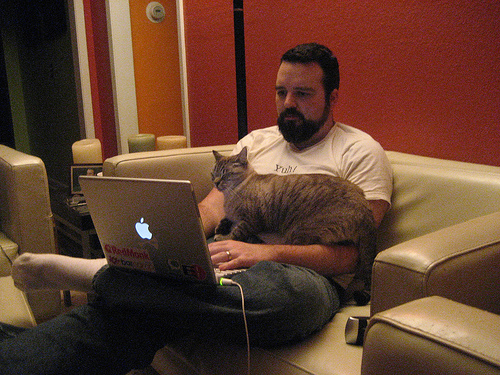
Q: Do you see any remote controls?
A: Yes, there is a remote control.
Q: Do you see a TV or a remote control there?
A: Yes, there is a remote control.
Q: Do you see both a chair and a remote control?
A: Yes, there are both a remote control and a chair.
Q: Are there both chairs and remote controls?
A: Yes, there are both a remote control and a chair.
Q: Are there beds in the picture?
A: No, there are no beds.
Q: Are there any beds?
A: No, there are no beds.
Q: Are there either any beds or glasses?
A: No, there are no beds or glasses.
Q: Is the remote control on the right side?
A: Yes, the remote control is on the right of the image.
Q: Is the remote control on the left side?
A: No, the remote control is on the right of the image.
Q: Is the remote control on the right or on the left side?
A: The remote control is on the right of the image.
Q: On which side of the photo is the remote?
A: The remote is on the right of the image.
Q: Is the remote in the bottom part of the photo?
A: Yes, the remote is in the bottom of the image.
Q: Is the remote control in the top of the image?
A: No, the remote control is in the bottom of the image.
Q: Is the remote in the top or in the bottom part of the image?
A: The remote is in the bottom of the image.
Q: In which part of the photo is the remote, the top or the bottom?
A: The remote is in the bottom of the image.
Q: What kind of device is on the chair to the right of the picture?
A: The device is a remote control.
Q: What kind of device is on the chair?
A: The device is a remote control.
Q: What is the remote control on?
A: The remote control is on the chair.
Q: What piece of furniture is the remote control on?
A: The remote control is on the chair.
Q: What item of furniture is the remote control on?
A: The remote control is on the chair.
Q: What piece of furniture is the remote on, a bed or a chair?
A: The remote is on a chair.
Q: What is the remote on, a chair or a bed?
A: The remote is on a chair.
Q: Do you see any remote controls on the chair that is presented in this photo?
A: Yes, there is a remote control on the chair.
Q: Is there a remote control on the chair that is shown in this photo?
A: Yes, there is a remote control on the chair.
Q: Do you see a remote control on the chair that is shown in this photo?
A: Yes, there is a remote control on the chair.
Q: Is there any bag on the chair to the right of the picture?
A: No, there is a remote control on the chair.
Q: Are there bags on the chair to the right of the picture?
A: No, there is a remote control on the chair.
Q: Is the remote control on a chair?
A: Yes, the remote control is on a chair.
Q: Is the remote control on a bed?
A: No, the remote control is on a chair.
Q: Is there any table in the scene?
A: Yes, there is a table.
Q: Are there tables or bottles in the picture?
A: Yes, there is a table.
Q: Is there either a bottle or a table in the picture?
A: Yes, there is a table.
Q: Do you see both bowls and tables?
A: No, there is a table but no bowls.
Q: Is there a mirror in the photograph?
A: No, there are no mirrors.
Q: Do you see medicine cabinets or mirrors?
A: No, there are no mirrors or medicine cabinets.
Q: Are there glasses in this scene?
A: No, there are no glasses.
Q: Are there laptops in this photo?
A: Yes, there is a laptop.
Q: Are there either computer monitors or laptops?
A: Yes, there is a laptop.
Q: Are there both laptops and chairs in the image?
A: Yes, there are both a laptop and a chair.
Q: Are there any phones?
A: No, there are no phones.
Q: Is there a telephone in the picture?
A: No, there are no phones.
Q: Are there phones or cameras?
A: No, there are no phones or cameras.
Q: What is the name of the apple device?
A: The device is a laptop.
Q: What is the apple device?
A: The device is a laptop.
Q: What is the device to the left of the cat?
A: The device is a laptop.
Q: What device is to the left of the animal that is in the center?
A: The device is a laptop.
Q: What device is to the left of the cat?
A: The device is a laptop.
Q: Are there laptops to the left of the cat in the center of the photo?
A: Yes, there is a laptop to the left of the cat.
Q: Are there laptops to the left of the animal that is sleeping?
A: Yes, there is a laptop to the left of the cat.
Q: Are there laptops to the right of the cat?
A: No, the laptop is to the left of the cat.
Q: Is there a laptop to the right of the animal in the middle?
A: No, the laptop is to the left of the cat.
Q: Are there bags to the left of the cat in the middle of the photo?
A: No, there is a laptop to the left of the cat.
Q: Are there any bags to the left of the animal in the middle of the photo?
A: No, there is a laptop to the left of the cat.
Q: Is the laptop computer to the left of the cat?
A: Yes, the laptop computer is to the left of the cat.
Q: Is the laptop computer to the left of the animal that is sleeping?
A: Yes, the laptop computer is to the left of the cat.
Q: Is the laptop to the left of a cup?
A: No, the laptop is to the left of the cat.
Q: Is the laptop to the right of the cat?
A: No, the laptop is to the left of the cat.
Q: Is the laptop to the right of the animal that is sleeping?
A: No, the laptop is to the left of the cat.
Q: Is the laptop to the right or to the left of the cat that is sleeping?
A: The laptop is to the left of the cat.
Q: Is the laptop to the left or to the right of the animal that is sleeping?
A: The laptop is to the left of the cat.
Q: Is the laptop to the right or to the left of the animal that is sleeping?
A: The laptop is to the left of the cat.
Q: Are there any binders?
A: No, there are no binders.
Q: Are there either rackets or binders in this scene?
A: No, there are no binders or rackets.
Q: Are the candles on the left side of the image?
A: Yes, the candles are on the left of the image.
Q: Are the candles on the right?
A: No, the candles are on the left of the image.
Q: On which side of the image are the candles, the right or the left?
A: The candles are on the left of the image.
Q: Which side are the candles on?
A: The candles are on the left of the image.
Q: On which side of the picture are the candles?
A: The candles are on the left of the image.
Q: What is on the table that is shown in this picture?
A: The candles are on the table.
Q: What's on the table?
A: The candles are on the table.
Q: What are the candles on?
A: The candles are on the table.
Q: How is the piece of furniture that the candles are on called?
A: The piece of furniture is a table.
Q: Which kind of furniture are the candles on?
A: The candles are on the table.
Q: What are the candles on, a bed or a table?
A: The candles are on a table.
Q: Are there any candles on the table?
A: Yes, there are candles on the table.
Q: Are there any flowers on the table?
A: No, there are candles on the table.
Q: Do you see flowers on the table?
A: No, there are candles on the table.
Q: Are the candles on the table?
A: Yes, the candles are on the table.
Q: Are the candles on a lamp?
A: No, the candles are on the table.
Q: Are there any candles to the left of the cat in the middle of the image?
A: Yes, there are candles to the left of the cat.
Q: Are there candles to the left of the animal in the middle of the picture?
A: Yes, there are candles to the left of the cat.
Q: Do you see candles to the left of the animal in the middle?
A: Yes, there are candles to the left of the cat.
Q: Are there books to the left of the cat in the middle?
A: No, there are candles to the left of the cat.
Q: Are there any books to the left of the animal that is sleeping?
A: No, there are candles to the left of the cat.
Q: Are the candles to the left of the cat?
A: Yes, the candles are to the left of the cat.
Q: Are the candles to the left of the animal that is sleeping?
A: Yes, the candles are to the left of the cat.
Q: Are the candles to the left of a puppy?
A: No, the candles are to the left of the cat.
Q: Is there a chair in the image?
A: Yes, there is a chair.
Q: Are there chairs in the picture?
A: Yes, there is a chair.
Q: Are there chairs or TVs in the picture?
A: Yes, there is a chair.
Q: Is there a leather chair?
A: Yes, there is a chair that is made of leather.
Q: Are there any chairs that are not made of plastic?
A: Yes, there is a chair that is made of leather.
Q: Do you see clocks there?
A: No, there are no clocks.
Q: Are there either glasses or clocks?
A: No, there are no clocks or glasses.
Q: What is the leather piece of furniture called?
A: The piece of furniture is a chair.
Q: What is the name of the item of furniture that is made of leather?
A: The piece of furniture is a chair.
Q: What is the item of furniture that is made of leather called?
A: The piece of furniture is a chair.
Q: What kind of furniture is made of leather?
A: The furniture is a chair.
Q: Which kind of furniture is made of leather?
A: The furniture is a chair.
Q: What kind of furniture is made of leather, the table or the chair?
A: The chair is made of leather.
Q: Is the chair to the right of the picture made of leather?
A: Yes, the chair is made of leather.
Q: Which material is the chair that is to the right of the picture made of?
A: The chair is made of leather.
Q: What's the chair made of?
A: The chair is made of leather.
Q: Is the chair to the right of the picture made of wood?
A: No, the chair is made of leather.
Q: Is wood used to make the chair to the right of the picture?
A: No, the chair is made of leather.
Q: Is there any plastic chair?
A: No, there is a chair but it is made of leather.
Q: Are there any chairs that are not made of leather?
A: No, there is a chair but it is made of leather.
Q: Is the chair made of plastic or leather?
A: The chair is made of leather.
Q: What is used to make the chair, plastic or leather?
A: The chair is made of leather.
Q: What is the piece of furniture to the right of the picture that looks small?
A: The piece of furniture is a chair.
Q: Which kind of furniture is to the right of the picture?
A: The piece of furniture is a chair.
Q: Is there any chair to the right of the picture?
A: Yes, there is a chair to the right of the picture.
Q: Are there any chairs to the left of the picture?
A: No, the chair is to the right of the picture.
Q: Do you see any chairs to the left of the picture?
A: No, the chair is to the right of the picture.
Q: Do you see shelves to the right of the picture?
A: No, there is a chair to the right of the picture.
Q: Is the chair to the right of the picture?
A: Yes, the chair is to the right of the picture.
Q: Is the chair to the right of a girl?
A: No, the chair is to the right of the picture.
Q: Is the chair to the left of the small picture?
A: No, the chair is to the right of the picture.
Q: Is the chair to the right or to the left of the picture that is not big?
A: The chair is to the right of the picture.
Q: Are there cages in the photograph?
A: No, there are no cages.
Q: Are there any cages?
A: No, there are no cages.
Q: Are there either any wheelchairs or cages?
A: No, there are no cages or wheelchairs.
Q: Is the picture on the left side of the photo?
A: Yes, the picture is on the left of the image.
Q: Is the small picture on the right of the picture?
A: No, the picture is on the left of the image.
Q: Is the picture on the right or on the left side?
A: The picture is on the left of the image.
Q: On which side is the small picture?
A: The picture is on the left of the image.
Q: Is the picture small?
A: Yes, the picture is small.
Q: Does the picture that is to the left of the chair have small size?
A: Yes, the picture is small.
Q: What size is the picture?
A: The picture is small.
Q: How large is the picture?
A: The picture is small.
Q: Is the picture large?
A: No, the picture is small.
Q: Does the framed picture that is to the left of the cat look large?
A: No, the picture is small.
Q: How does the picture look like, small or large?
A: The picture is small.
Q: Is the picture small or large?
A: The picture is small.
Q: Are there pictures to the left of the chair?
A: Yes, there is a picture to the left of the chair.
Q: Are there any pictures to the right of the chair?
A: No, the picture is to the left of the chair.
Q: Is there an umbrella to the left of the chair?
A: No, there is a picture to the left of the chair.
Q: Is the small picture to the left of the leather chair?
A: Yes, the picture is to the left of the chair.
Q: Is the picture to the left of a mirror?
A: No, the picture is to the left of the chair.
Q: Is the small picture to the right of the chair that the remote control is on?
A: No, the picture is to the left of the chair.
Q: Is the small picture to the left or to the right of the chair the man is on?
A: The picture is to the left of the chair.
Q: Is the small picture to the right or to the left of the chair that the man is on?
A: The picture is to the left of the chair.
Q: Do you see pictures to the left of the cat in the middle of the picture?
A: Yes, there is a picture to the left of the cat.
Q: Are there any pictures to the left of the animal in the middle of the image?
A: Yes, there is a picture to the left of the cat.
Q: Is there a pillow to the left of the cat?
A: No, there is a picture to the left of the cat.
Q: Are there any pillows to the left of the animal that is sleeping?
A: No, there is a picture to the left of the cat.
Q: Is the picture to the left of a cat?
A: Yes, the picture is to the left of a cat.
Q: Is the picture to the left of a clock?
A: No, the picture is to the left of a cat.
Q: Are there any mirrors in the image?
A: No, there are no mirrors.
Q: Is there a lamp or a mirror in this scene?
A: No, there are no mirrors or lamps.